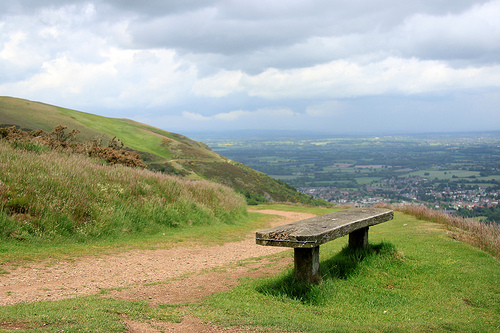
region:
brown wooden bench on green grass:
[246, 194, 413, 301]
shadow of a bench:
[258, 248, 402, 303]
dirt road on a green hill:
[41, 214, 266, 314]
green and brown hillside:
[18, 89, 212, 232]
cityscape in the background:
[295, 126, 487, 213]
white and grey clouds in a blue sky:
[207, 22, 395, 127]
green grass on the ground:
[331, 255, 397, 302]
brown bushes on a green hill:
[19, 120, 143, 165]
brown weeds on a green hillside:
[402, 200, 496, 255]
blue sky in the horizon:
[284, 101, 461, 143]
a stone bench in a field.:
[245, 191, 398, 301]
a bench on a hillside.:
[229, 194, 407, 298]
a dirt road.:
[0, 205, 321, 307]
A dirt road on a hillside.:
[0, 203, 317, 301]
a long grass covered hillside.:
[0, 90, 295, 246]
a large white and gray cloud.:
[0, 70, 497, 111]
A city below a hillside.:
[313, 170, 498, 227]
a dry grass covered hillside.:
[0, 132, 260, 229]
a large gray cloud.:
[0, 4, 206, 122]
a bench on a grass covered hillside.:
[246, 190, 403, 307]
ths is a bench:
[239, 196, 401, 279]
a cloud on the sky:
[240, 51, 322, 108]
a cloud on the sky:
[348, 28, 440, 108]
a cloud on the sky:
[96, 32, 205, 122]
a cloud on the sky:
[205, 48, 255, 114]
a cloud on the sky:
[44, 33, 119, 108]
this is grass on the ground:
[358, 266, 398, 308]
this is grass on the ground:
[427, 266, 496, 326]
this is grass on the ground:
[127, 162, 202, 240]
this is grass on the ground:
[18, 156, 108, 246]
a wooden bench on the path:
[222, 173, 432, 319]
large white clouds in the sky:
[0, 8, 417, 140]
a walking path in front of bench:
[0, 182, 335, 318]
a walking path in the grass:
[10, 200, 302, 330]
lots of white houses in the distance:
[325, 178, 497, 217]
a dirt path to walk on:
[22, 231, 235, 312]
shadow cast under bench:
[273, 234, 390, 306]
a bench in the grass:
[253, 188, 458, 308]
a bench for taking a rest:
[249, 173, 428, 306]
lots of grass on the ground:
[9, 88, 464, 331]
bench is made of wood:
[254, 205, 393, 285]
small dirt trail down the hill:
[1, 204, 316, 305]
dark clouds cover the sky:
[1, 1, 497, 128]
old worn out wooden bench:
[256, 208, 393, 284]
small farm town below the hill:
[193, 132, 498, 230]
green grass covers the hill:
[1, 95, 493, 331]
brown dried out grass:
[336, 203, 498, 261]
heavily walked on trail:
[1, 206, 318, 316]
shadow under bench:
[255, 242, 389, 306]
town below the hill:
[289, 184, 496, 228]